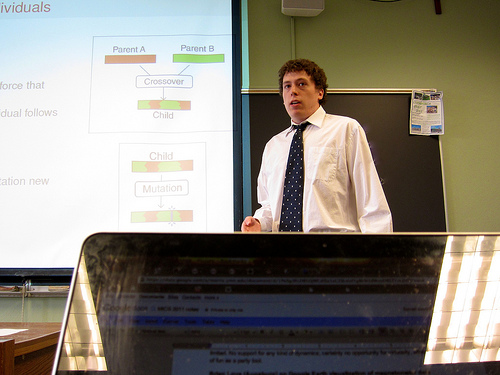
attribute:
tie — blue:
[277, 124, 313, 231]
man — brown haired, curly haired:
[245, 54, 396, 233]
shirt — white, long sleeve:
[241, 112, 396, 226]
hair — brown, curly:
[267, 49, 337, 102]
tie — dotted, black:
[281, 143, 306, 228]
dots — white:
[286, 182, 303, 193]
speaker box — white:
[271, 0, 325, 19]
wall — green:
[243, 7, 499, 232]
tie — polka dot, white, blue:
[278, 122, 309, 232]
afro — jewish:
[279, 58, 328, 84]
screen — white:
[4, 3, 241, 265]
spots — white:
[279, 120, 311, 230]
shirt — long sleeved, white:
[246, 107, 397, 232]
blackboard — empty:
[233, 81, 456, 225]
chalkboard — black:
[240, 85, 450, 235]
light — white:
[422, 234, 498, 368]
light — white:
[55, 249, 105, 372]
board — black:
[238, 86, 448, 235]